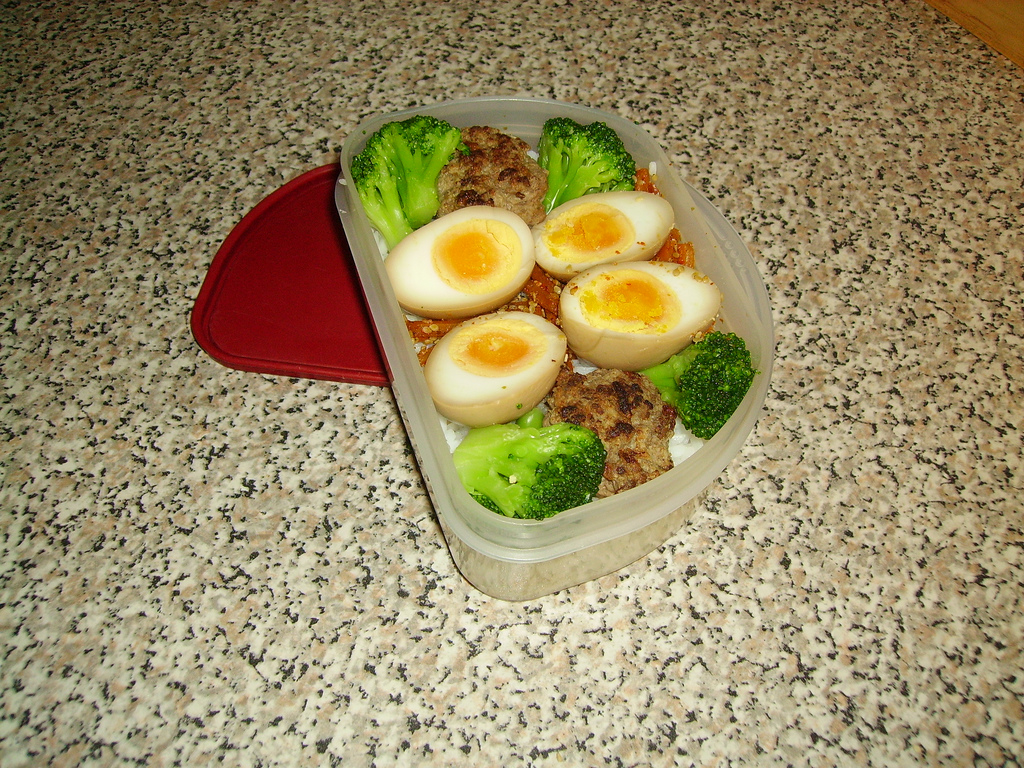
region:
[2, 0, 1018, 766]
countertop with a granite type pattern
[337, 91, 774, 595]
plastic container holding food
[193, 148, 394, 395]
red lid on the countertop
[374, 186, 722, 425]
sliced eggs in the middle of the container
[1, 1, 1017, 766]
plastic container on a countertop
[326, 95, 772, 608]
brocoli inside a plastic container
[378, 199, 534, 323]
white and golden colored hard-boiled egg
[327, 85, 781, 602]
dinner inside a tupperware container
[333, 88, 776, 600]
green veggies in each corner of a container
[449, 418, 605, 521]
bright green vegetable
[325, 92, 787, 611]
a plastic container holding assorted food inside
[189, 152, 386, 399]
part of the lid for the plastic container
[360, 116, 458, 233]
a piece of broccoli in the corner of the container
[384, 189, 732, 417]
two potatoes sliced in half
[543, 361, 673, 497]
a piece of steak sitting in the middle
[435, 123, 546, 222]
another piece of steak sitting in the middle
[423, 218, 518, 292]
the yellow part in one of the potato slices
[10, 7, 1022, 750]
the counter that the plastic container is sitting on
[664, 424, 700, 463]
some rice underneath the other food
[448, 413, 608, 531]
Green cooked broccoli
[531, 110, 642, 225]
Green cooked broccoli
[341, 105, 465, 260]
Green cooked broccoli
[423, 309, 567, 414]
Half of an egg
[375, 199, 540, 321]
Half of an egg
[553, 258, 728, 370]
Half of an egg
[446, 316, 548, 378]
Yolk of an egg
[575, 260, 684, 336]
York of an egg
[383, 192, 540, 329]
one half of an egg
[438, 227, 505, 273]
the yellow yolk of an egg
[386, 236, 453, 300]
the white yolk of an egg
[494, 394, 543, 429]
the brown outside of an egg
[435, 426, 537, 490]
the green stem of a broccoli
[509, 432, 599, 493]
the green bush of a broccoli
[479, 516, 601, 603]
a clear Tupperware bowl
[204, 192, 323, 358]
the red lid of a tupperware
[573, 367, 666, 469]
a brown piece of meat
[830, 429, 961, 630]
the speckled top of a counter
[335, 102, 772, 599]
food in plastic container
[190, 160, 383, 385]
inside of red plastic cover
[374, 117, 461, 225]
broccoli of cut tip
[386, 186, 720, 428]
four halves of cooked egg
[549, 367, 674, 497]
surface of cooked meat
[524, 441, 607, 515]
green floret of broccoli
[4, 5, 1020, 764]
surface of marble table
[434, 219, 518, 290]
cracked dried egg yolk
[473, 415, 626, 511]
The broccoli is green.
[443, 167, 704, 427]
Food in the plastic container.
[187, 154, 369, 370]
The lid of the container is red.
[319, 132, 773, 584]
The container is clear.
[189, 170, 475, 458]
The lid is under the container.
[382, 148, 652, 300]
Eggs and broccoli in the container.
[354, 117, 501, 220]
The vegetable is broccoli.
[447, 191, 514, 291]
egg in a bowl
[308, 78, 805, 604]
plastic container on table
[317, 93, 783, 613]
container on table is plastic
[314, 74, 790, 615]
container on table holds food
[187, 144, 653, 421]
lid on table is red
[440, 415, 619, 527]
broccoli in plastic container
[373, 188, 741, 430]
boiled egg in plastic container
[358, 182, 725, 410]
egg in container is boiled